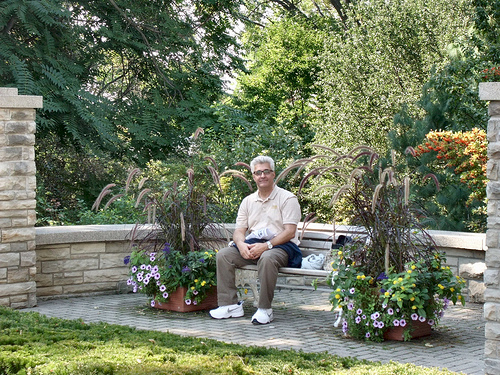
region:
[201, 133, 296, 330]
man sitting on a bench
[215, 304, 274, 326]
white nike shoes on man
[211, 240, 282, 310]
grey pants on legs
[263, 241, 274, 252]
small watch on wrist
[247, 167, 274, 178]
black glasses on face of man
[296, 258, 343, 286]
white bench below man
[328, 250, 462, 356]
planter filled with plants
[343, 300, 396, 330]
purple flowers in planter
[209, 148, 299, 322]
man sitting on garden bench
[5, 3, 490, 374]
beautiful, lush garden with stone sitting area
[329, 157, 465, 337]
brown planter box planted with flowers and grasses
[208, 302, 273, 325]
white Nike running shoes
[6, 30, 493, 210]
green trees behind man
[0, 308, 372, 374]
short green grass near gray pavers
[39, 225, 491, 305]
low brick light gray brick wall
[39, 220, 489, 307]
low brick wall is slightly curved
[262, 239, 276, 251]
silver watch on left wrist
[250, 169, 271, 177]
dark framed glasses with clear lenses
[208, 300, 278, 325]
Man wearing shoes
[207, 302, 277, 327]
Man is wearing shoes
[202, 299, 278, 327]
Man wearing white shoes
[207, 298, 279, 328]
Man is wearing white shoes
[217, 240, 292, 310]
Man wearing pants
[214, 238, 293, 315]
Man is wearing pants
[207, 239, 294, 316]
Man wearing gray pants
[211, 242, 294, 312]
Man is wearing gray pants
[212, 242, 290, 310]
Man wearing dark gray pants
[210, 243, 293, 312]
Man is wearing dark gray pants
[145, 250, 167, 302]
There are flowers that are visible here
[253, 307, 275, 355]
There are white Nikes here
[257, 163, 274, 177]
This person is wearing glasses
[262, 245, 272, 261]
This person is wearing a watch here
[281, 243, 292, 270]
This person has a dark blue jacket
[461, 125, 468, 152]
There are orange flowers here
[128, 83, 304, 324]
This photo has a great deal of detail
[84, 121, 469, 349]
a man sitting in a garden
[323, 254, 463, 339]
flowers in a pot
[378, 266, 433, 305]
yellow flowers and green leaves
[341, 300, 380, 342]
purple flowers and green leaves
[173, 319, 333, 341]
brick pavers on the grounc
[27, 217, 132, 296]
a stone wall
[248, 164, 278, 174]
a man wearing glasses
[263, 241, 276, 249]
a watch on an arm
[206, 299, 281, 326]
tennis shoes on feet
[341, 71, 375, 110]
green leaves on the tree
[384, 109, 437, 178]
green leaves on the tree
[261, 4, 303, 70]
green leaves on the tree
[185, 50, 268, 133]
green leaves on the tree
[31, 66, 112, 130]
green leaves on the tree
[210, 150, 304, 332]
a person is sitting down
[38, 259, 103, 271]
a stone in a wall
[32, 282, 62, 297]
a stone in a wall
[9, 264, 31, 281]
a stone in a wall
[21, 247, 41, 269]
a stone in a wall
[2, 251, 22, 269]
a stone in a wall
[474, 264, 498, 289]
a stone in a wall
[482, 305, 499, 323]
a stone in a wall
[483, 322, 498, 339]
a stone in a wall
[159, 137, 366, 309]
man sitting down on seat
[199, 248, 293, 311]
legs of the man